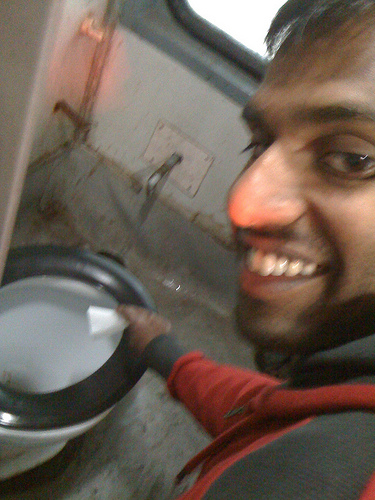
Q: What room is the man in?
A: Bathroom.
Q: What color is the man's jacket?
A: Red and grey.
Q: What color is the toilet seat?
A: Black.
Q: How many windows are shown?
A: One.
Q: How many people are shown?
A: One.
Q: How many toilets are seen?
A: One.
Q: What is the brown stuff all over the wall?
A: Rust.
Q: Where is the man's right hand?
A: Near toilet.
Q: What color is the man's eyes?
A: Brown.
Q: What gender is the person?
A: Male.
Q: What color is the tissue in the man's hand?
A: White.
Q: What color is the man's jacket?
A: Black and red.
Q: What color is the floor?
A: Grey.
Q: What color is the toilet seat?
A: Black.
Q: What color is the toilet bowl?
A: White.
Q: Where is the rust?
A: In the corner of the room.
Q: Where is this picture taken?
A: Bathroom.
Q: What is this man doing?
A: Wiping the toilet seat.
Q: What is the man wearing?
A: A sweater.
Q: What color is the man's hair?
A: Black.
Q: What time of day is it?
A: Day time.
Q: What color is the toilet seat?
A: Black.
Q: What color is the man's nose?
A: Brownish red.